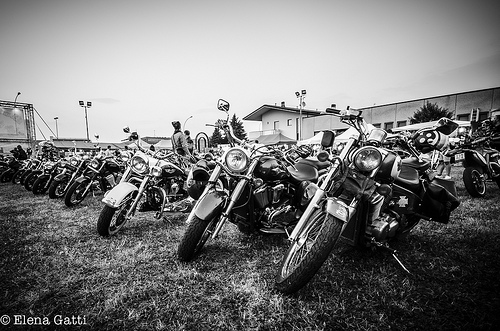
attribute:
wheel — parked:
[272, 204, 344, 292]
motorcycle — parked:
[275, 107, 459, 290]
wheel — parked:
[181, 193, 227, 267]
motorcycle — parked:
[174, 98, 340, 265]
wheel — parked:
[93, 184, 139, 238]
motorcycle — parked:
[93, 125, 204, 235]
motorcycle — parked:
[454, 141, 499, 195]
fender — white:
[324, 194, 351, 229]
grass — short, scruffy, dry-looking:
[0, 124, 496, 328]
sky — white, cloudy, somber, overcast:
[2, 1, 499, 144]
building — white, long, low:
[238, 83, 497, 136]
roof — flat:
[243, 100, 322, 123]